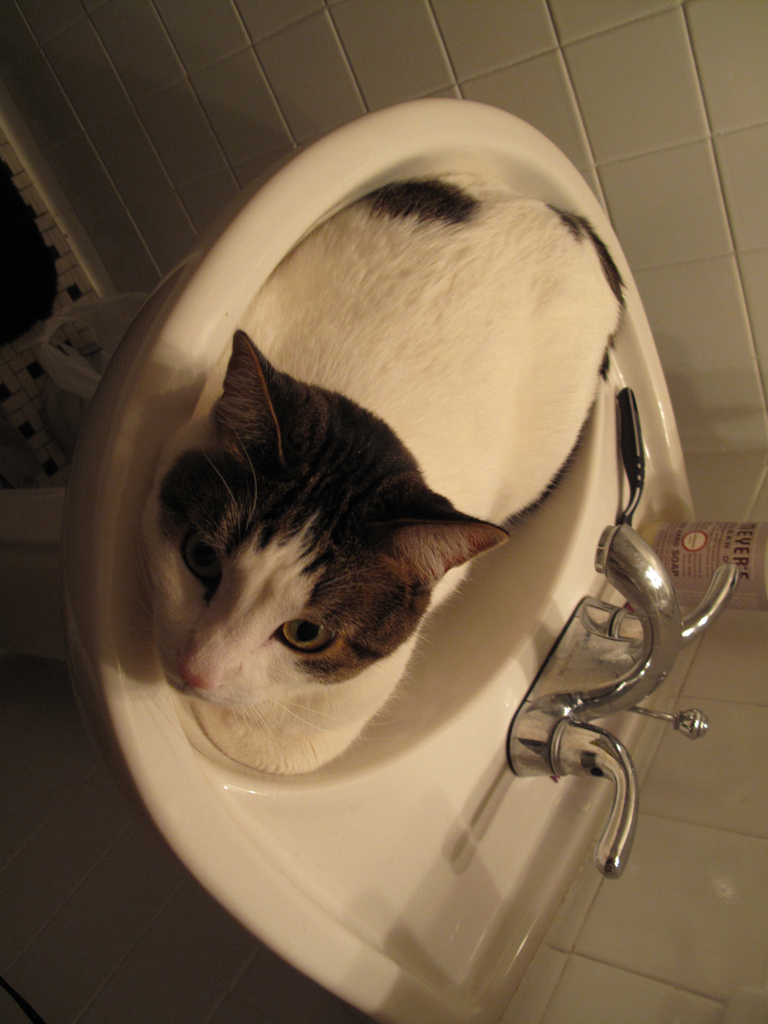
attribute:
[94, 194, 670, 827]
cat — brown, white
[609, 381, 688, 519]
handle — black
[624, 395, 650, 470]
line — gray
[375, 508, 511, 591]
cat's ear — with hair inside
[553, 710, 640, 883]
faucet switch — stainless steel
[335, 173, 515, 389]
white hair — with black spot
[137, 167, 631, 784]
multi-colored cat — lying down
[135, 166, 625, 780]
cat — lying down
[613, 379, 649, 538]
razor blade — for shaving